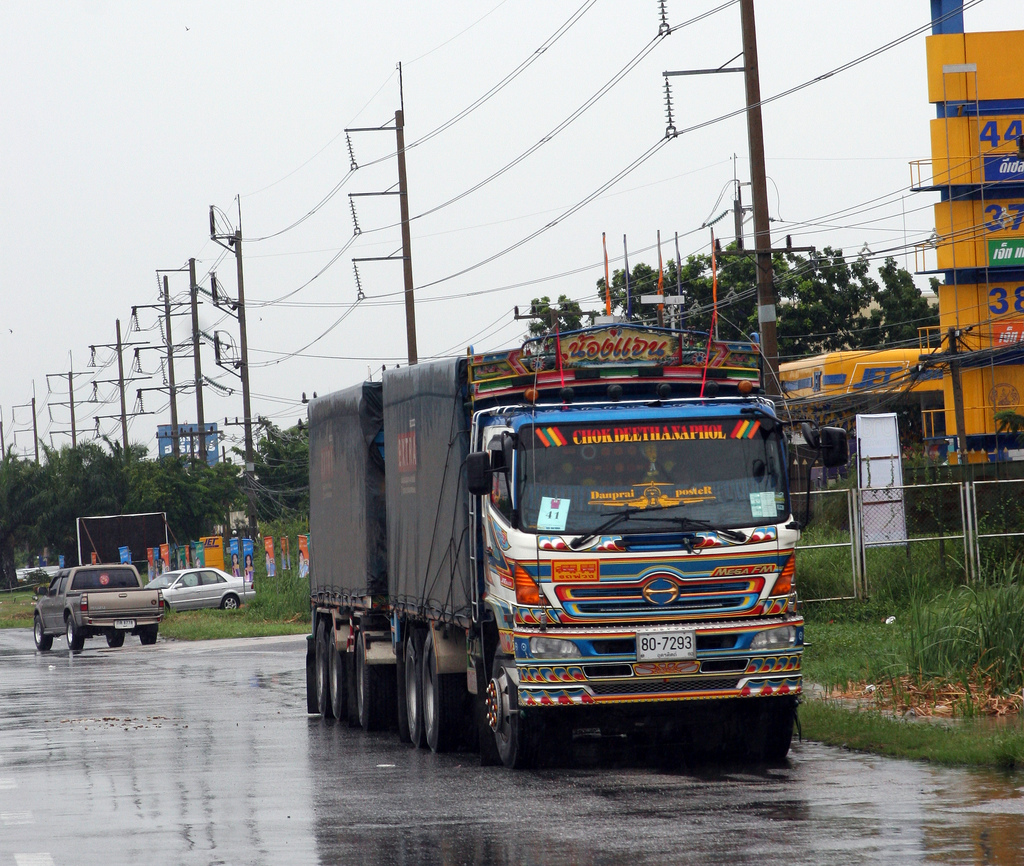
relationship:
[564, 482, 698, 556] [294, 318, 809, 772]
wiper on truck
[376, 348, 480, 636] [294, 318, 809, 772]
tarp on truck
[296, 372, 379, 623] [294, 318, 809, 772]
tarp on truck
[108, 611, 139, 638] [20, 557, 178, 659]
plate on truck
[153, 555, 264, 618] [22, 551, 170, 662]
car in front of truck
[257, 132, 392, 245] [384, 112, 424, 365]
wire on pole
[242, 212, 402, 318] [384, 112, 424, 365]
wire on pole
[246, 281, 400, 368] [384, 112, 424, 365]
wire on pole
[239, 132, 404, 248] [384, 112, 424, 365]
wire on pole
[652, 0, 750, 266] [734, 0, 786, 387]
wires on pole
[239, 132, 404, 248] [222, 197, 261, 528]
wire on pole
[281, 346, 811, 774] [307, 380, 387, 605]
semi has tarp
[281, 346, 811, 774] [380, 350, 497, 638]
semi has trailer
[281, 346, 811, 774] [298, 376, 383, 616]
semi has trailer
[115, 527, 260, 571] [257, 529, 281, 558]
line has flag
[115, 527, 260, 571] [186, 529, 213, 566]
line has flag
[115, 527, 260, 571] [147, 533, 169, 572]
line has flag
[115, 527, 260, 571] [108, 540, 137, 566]
line has flag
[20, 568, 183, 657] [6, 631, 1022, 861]
truck on road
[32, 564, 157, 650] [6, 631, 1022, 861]
truck on road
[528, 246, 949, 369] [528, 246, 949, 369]
leaves on leaves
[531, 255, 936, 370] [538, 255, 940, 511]
leaves on tree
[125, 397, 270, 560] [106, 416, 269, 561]
leaves on tree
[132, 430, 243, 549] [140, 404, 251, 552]
leaves on tree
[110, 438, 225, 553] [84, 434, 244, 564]
leaves on tree